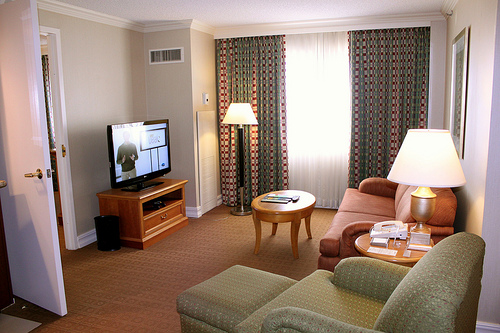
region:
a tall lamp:
[226, 100, 261, 215]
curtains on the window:
[353, 33, 424, 183]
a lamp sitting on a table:
[389, 120, 461, 240]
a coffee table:
[249, 182, 318, 247]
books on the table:
[262, 190, 294, 205]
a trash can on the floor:
[98, 213, 128, 250]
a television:
[101, 121, 176, 182]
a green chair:
[178, 247, 493, 330]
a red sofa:
[334, 182, 446, 230]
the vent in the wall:
[146, 48, 186, 63]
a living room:
[1, 2, 498, 330]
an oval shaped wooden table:
[248, 190, 315, 256]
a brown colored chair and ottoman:
[174, 229, 489, 331]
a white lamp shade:
[387, 127, 467, 189]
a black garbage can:
[93, 213, 118, 252]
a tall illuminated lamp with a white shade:
[222, 103, 257, 218]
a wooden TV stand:
[96, 174, 188, 248]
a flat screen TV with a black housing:
[107, 115, 174, 195]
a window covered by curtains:
[212, 27, 431, 206]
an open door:
[4, 1, 73, 316]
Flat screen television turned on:
[105, 117, 173, 194]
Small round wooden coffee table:
[248, 186, 314, 260]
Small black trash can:
[91, 212, 127, 254]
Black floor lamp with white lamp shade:
[222, 99, 258, 216]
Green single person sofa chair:
[170, 227, 485, 328]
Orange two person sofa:
[314, 176, 457, 275]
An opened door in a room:
[2, 1, 79, 318]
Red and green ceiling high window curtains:
[213, 23, 431, 211]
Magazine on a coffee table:
[259, 191, 291, 203]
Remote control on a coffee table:
[290, 193, 299, 203]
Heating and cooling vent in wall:
[145, 49, 185, 66]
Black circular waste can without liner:
[94, 212, 122, 254]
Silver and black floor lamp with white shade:
[223, 102, 255, 217]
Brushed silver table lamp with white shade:
[390, 126, 465, 233]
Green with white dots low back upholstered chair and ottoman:
[175, 232, 484, 330]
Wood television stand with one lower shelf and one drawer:
[97, 176, 188, 250]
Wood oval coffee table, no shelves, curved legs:
[248, 188, 312, 258]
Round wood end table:
[355, 226, 436, 266]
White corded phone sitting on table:
[370, 219, 410, 239]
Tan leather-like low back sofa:
[320, 177, 455, 267]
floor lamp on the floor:
[206, 83, 271, 241]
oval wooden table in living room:
[225, 161, 323, 282]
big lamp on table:
[372, 114, 479, 271]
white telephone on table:
[360, 208, 422, 254]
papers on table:
[365, 225, 453, 270]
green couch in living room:
[145, 219, 499, 331]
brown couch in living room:
[312, 153, 469, 293]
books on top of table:
[256, 188, 303, 214]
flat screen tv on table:
[91, 104, 193, 194]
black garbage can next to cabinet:
[82, 201, 134, 264]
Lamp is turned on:
[218, 96, 265, 176]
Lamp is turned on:
[221, 99, 263, 187]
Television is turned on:
[102, 116, 177, 196]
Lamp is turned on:
[383, 123, 471, 239]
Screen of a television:
[114, 128, 169, 172]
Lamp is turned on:
[221, 100, 266, 164]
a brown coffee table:
[246, 186, 316, 265]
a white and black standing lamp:
[221, 102, 259, 219]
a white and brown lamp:
[386, 128, 467, 230]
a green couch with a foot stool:
[176, 231, 486, 329]